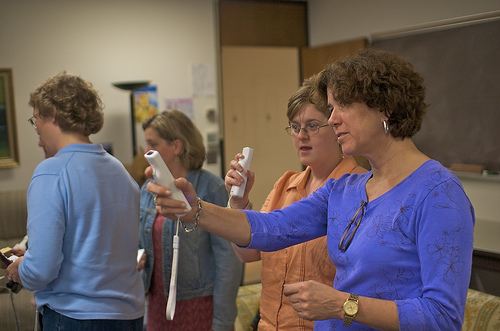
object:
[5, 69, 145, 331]
people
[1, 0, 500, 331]
room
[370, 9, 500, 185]
blackboard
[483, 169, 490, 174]
eraser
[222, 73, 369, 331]
woman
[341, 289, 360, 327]
watch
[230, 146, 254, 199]
game control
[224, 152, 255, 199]
hand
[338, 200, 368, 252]
glasses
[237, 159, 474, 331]
shirt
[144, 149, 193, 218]
game control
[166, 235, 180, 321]
handle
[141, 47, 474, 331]
woman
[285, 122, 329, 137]
glasses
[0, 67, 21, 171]
picture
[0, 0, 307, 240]
wall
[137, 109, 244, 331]
woman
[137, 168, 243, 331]
jacket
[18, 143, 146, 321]
shirt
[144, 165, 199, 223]
hand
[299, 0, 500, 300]
wall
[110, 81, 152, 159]
floor lamp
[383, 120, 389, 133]
earring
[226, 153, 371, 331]
shirt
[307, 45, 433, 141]
hair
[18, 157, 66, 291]
long sleeve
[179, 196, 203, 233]
bracelet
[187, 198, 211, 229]
wrist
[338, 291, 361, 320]
wrist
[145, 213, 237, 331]
dress